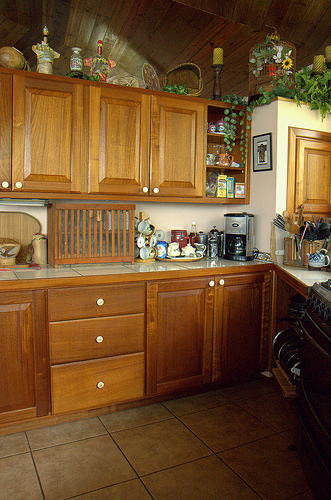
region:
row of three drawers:
[47, 286, 155, 417]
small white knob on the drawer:
[94, 381, 107, 389]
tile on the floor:
[2, 382, 314, 499]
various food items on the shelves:
[204, 105, 249, 199]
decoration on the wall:
[249, 131, 274, 176]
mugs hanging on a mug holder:
[129, 209, 155, 261]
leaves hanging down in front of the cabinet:
[217, 98, 255, 170]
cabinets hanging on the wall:
[0, 65, 255, 204]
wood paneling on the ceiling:
[1, 1, 328, 100]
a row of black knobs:
[305, 297, 327, 321]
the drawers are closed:
[48, 283, 152, 413]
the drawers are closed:
[28, 273, 159, 434]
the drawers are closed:
[46, 290, 142, 423]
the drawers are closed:
[41, 279, 158, 440]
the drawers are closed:
[40, 273, 168, 440]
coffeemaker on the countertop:
[211, 202, 270, 294]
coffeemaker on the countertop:
[200, 201, 263, 276]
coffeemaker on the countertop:
[210, 205, 276, 300]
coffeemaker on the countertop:
[209, 204, 269, 284]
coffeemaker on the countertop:
[217, 212, 263, 274]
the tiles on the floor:
[0, 377, 316, 499]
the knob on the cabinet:
[218, 279, 223, 285]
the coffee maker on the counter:
[221, 212, 253, 260]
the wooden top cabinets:
[0, 66, 251, 204]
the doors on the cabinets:
[0, 73, 204, 197]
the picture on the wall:
[252, 133, 271, 171]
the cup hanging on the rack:
[137, 217, 154, 236]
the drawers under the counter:
[46, 283, 146, 414]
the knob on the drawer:
[96, 298, 103, 305]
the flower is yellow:
[282, 59, 294, 67]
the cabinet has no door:
[212, 114, 243, 192]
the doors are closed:
[203, 277, 230, 322]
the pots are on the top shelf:
[276, 298, 304, 328]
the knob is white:
[93, 296, 107, 306]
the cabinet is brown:
[166, 297, 187, 326]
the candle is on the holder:
[213, 43, 224, 80]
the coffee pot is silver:
[228, 217, 243, 229]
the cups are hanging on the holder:
[137, 208, 153, 255]